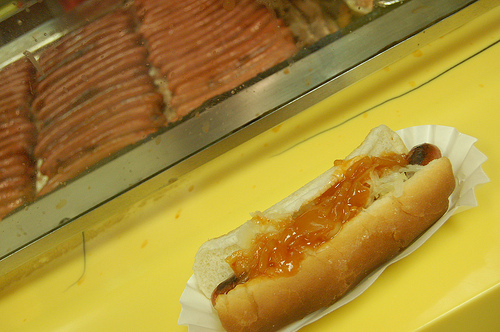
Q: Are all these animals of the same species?
A: Yes, all the animals are dogs.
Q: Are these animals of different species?
A: No, all the animals are dogs.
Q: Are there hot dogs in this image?
A: Yes, there is a hot dog.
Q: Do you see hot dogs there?
A: Yes, there is a hot dog.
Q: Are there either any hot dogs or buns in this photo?
A: Yes, there is a hot dog.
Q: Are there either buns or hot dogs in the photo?
A: Yes, there is a hot dog.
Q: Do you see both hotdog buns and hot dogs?
A: Yes, there are both a hot dog and a hotdog bun.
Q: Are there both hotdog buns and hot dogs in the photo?
A: Yes, there are both a hot dog and a hotdog bun.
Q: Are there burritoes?
A: No, there are no burritoes.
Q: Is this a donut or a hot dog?
A: This is a hot dog.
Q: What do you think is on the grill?
A: The hot dog is on the grill.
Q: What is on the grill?
A: The hot dog is on the grill.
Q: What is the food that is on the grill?
A: The food is a hot dog.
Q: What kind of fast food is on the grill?
A: The food is a hot dog.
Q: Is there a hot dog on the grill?
A: Yes, there is a hot dog on the grill.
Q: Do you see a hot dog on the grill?
A: Yes, there is a hot dog on the grill.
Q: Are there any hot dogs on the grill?
A: Yes, there is a hot dog on the grill.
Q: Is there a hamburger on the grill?
A: No, there is a hot dog on the grill.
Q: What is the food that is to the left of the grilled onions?
A: The food is a hot dog.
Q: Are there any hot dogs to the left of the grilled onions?
A: Yes, there is a hot dog to the left of the onions.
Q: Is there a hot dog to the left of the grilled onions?
A: Yes, there is a hot dog to the left of the onions.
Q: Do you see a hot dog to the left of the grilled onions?
A: Yes, there is a hot dog to the left of the onions.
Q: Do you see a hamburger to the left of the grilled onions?
A: No, there is a hot dog to the left of the onions.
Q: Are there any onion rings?
A: No, there are no onion rings.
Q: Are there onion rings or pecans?
A: No, there are no onion rings or pecans.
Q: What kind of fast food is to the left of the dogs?
A: The food is hot dogs.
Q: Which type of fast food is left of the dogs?
A: The food is hot dogs.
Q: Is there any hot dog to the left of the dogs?
A: Yes, there are hot dogs to the left of the dogs.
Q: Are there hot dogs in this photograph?
A: Yes, there is a hot dog.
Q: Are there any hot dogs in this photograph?
A: Yes, there is a hot dog.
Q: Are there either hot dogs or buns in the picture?
A: Yes, there is a hot dog.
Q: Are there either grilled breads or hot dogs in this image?
A: Yes, there is a grilled hot dog.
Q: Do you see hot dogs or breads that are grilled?
A: Yes, the hot dog is grilled.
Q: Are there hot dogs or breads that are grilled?
A: Yes, the hot dog is grilled.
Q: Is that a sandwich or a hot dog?
A: That is a hot dog.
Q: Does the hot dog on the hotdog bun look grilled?
A: Yes, the hot dog is grilled.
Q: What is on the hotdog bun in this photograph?
A: The hot dog is on the hotdog bun.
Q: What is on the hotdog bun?
A: The hot dog is on the hotdog bun.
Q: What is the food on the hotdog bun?
A: The food is a hot dog.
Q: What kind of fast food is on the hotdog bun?
A: The food is a hot dog.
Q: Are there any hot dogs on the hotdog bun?
A: Yes, there is a hot dog on the hotdog bun.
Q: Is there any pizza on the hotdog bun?
A: No, there is a hot dog on the hotdog bun.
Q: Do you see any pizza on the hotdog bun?
A: No, there is a hot dog on the hotdog bun.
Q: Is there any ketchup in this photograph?
A: Yes, there is ketchup.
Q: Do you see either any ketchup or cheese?
A: Yes, there is ketchup.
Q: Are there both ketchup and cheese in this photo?
A: No, there is ketchup but no cheese.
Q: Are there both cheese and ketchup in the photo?
A: No, there is ketchup but no cheese.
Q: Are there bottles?
A: No, there are no bottles.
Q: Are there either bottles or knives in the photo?
A: No, there are no bottles or knives.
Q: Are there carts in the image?
A: No, there are no carts.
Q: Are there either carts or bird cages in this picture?
A: No, there are no carts or bird cages.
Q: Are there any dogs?
A: Yes, there are dogs.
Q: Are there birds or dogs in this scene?
A: Yes, there are dogs.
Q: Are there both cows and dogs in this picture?
A: No, there are dogs but no cows.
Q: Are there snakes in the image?
A: No, there are no snakes.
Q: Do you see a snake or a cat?
A: No, there are no snakes or cats.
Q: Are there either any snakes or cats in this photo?
A: No, there are no snakes or cats.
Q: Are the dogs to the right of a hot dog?
A: Yes, the dogs are to the right of a hot dog.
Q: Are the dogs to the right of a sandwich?
A: No, the dogs are to the right of a hot dog.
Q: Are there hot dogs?
A: Yes, there is a hot dog.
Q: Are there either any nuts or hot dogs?
A: Yes, there is a hot dog.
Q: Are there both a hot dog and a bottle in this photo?
A: No, there is a hot dog but no bottles.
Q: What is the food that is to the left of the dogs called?
A: The food is a hot dog.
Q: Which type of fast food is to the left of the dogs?
A: The food is a hot dog.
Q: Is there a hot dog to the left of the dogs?
A: Yes, there is a hot dog to the left of the dogs.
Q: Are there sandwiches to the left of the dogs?
A: No, there is a hot dog to the left of the dogs.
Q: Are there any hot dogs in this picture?
A: Yes, there is a hot dog.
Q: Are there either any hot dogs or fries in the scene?
A: Yes, there is a hot dog.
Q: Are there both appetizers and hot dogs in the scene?
A: No, there is a hot dog but no appetizers.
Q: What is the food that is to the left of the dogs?
A: The food is a hot dog.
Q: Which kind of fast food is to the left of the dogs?
A: The food is a hot dog.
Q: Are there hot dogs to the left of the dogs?
A: Yes, there is a hot dog to the left of the dogs.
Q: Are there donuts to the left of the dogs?
A: No, there is a hot dog to the left of the dogs.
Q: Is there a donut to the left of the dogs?
A: No, there is a hot dog to the left of the dogs.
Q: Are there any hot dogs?
A: Yes, there is a hot dog.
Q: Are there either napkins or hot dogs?
A: Yes, there is a hot dog.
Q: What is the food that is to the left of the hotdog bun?
A: The food is a hot dog.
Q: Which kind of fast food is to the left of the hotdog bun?
A: The food is a hot dog.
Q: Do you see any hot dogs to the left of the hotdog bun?
A: Yes, there is a hot dog to the left of the hotdog bun.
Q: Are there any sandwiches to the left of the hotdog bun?
A: No, there is a hot dog to the left of the hotdog bun.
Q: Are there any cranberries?
A: No, there are no cranberries.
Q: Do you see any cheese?
A: No, there is no cheese.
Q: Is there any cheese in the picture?
A: No, there is no cheese.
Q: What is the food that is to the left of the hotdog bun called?
A: The food is hot dogs.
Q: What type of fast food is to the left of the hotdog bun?
A: The food is hot dogs.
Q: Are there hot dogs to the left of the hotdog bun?
A: Yes, there are hot dogs to the left of the hotdog bun.